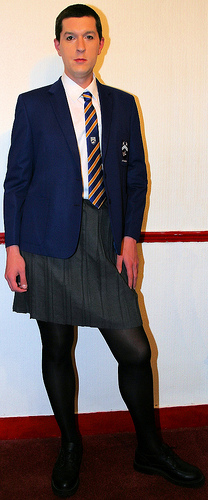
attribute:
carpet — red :
[172, 416, 193, 446]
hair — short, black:
[51, 2, 103, 38]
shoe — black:
[55, 440, 88, 493]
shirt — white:
[59, 72, 113, 201]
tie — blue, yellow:
[74, 88, 109, 210]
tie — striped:
[81, 87, 108, 209]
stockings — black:
[37, 320, 158, 439]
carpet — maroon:
[18, 429, 201, 495]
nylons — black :
[35, 327, 157, 443]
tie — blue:
[69, 83, 104, 206]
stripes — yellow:
[82, 154, 101, 183]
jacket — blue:
[3, 78, 148, 256]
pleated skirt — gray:
[9, 194, 155, 333]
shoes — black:
[53, 444, 199, 496]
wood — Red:
[1, 230, 207, 243]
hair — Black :
[53, 4, 102, 40]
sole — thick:
[130, 458, 206, 490]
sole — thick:
[47, 441, 81, 499]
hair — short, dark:
[53, 3, 102, 45]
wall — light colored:
[1, 0, 207, 418]